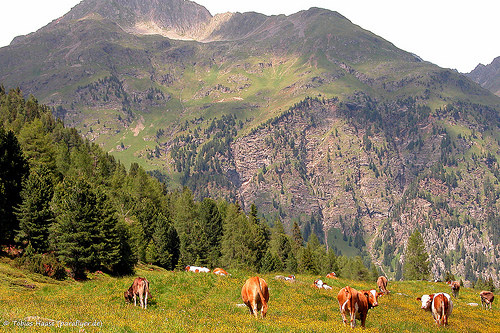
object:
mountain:
[0, 0, 498, 287]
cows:
[480, 290, 495, 311]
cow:
[240, 276, 269, 320]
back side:
[338, 285, 359, 317]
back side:
[434, 295, 449, 320]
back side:
[249, 275, 266, 310]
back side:
[140, 278, 152, 308]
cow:
[376, 276, 389, 295]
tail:
[255, 277, 268, 317]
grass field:
[1, 250, 498, 331]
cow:
[212, 267, 231, 276]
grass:
[1, 269, 498, 331]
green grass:
[30, 0, 472, 266]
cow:
[124, 276, 153, 309]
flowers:
[371, 301, 416, 323]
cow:
[185, 264, 211, 273]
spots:
[195, 269, 200, 273]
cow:
[312, 279, 333, 290]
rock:
[467, 303, 478, 307]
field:
[8, 260, 498, 331]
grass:
[250, 74, 281, 99]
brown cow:
[416, 292, 453, 329]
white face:
[421, 295, 431, 309]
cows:
[449, 281, 460, 298]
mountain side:
[1, 0, 498, 296]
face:
[368, 290, 380, 306]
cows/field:
[104, 265, 496, 330]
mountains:
[0, 1, 498, 158]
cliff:
[238, 104, 495, 276]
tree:
[50, 175, 127, 281]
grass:
[110, 90, 262, 125]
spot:
[370, 290, 377, 296]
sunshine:
[125, 11, 235, 50]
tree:
[393, 223, 440, 284]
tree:
[260, 250, 282, 279]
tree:
[169, 190, 209, 270]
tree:
[217, 191, 264, 278]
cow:
[337, 285, 384, 330]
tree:
[34, 112, 164, 244]